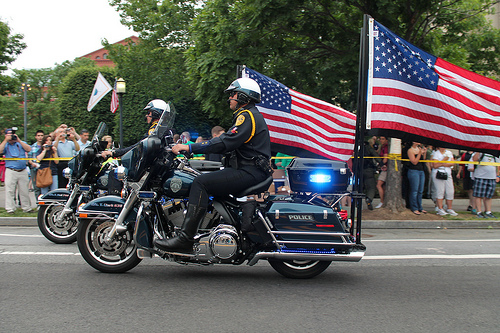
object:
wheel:
[76, 200, 146, 274]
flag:
[360, 18, 500, 157]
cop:
[152, 78, 276, 255]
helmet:
[224, 76, 264, 103]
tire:
[37, 201, 84, 245]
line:
[362, 252, 500, 261]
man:
[0, 128, 37, 214]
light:
[20, 82, 33, 148]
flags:
[87, 71, 116, 112]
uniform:
[188, 108, 274, 205]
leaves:
[217, 20, 228, 32]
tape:
[354, 153, 500, 172]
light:
[308, 171, 333, 184]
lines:
[0, 249, 88, 256]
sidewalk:
[0, 197, 500, 227]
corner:
[1, 210, 29, 240]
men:
[100, 98, 172, 159]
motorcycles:
[35, 133, 177, 244]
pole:
[352, 18, 370, 240]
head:
[227, 86, 261, 108]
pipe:
[250, 249, 363, 267]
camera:
[8, 126, 24, 142]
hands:
[0, 127, 13, 139]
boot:
[155, 195, 213, 255]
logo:
[289, 213, 320, 221]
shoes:
[433, 208, 454, 216]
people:
[35, 134, 60, 193]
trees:
[58, 65, 118, 140]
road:
[0, 221, 500, 333]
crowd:
[428, 147, 458, 216]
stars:
[405, 74, 412, 79]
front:
[16, 165, 170, 274]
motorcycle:
[72, 129, 367, 276]